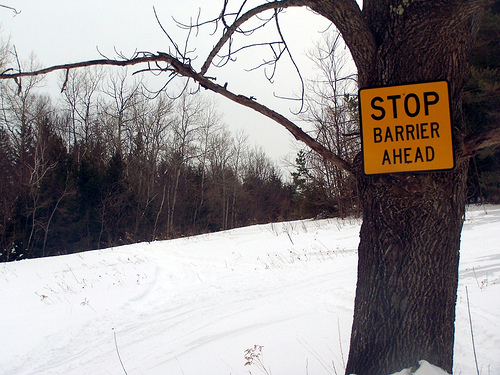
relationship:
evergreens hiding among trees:
[4, 118, 140, 259] [2, 90, 294, 262]